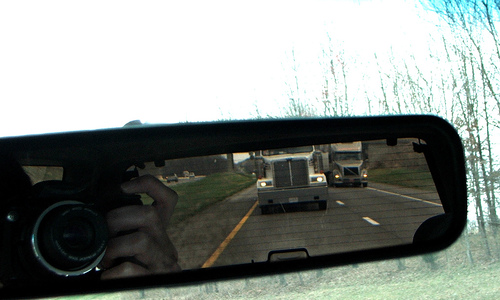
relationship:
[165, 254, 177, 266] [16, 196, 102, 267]
person holding camera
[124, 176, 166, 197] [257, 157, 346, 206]
finger on semi truck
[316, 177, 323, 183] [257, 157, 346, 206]
headlights on semi truck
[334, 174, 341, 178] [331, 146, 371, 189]
headlights on semi truck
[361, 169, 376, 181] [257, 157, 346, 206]
light on semi truck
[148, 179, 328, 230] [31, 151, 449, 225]
reflection in mirror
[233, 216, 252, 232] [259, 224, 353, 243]
stripe on road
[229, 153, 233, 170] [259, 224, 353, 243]
tree along road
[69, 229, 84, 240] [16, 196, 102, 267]
lens of camera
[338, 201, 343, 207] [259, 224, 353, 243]
line on road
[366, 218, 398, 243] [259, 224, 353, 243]
line on road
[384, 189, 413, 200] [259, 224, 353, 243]
line on road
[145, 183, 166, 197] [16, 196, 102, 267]
finger holding camera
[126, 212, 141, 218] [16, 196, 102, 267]
finger holding camera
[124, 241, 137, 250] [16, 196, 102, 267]
finger holding camera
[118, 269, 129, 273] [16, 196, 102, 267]
finger holding camera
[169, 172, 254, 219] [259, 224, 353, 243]
grass between road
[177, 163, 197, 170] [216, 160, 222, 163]
tree in background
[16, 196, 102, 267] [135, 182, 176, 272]
camera in hand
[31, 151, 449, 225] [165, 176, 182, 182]
mirror in car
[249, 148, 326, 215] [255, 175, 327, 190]
trucks with headlights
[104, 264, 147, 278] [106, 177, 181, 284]
finger connected to hand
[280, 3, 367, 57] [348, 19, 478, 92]
sun glaring through trees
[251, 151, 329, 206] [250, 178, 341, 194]
truck has headlights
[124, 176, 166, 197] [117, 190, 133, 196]
finger sitting on button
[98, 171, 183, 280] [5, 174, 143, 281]
hand holding camera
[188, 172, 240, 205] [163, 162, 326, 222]
grass next to street